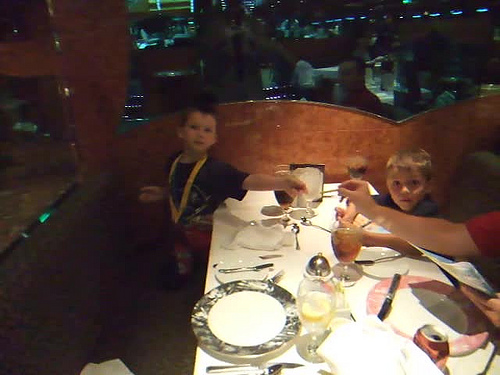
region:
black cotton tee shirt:
[164, 159, 246, 227]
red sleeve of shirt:
[467, 205, 499, 254]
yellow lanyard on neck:
[163, 154, 210, 226]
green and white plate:
[195, 280, 299, 357]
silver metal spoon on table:
[303, 219, 330, 238]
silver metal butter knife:
[379, 272, 400, 319]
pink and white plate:
[368, 275, 492, 355]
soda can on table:
[411, 324, 450, 371]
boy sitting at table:
[366, 149, 442, 220]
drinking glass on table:
[331, 222, 363, 285]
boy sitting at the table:
[157, 103, 255, 250]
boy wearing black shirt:
[144, 94, 255, 254]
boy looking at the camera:
[366, 134, 438, 241]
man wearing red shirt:
[322, 48, 392, 129]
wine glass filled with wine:
[290, 269, 340, 360]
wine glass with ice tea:
[330, 211, 375, 286]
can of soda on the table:
[409, 318, 453, 363]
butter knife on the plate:
[217, 256, 282, 280]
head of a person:
[174, 92, 228, 157]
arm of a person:
[132, 173, 172, 213]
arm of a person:
[220, 149, 284, 203]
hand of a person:
[280, 159, 315, 197]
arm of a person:
[374, 191, 468, 255]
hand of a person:
[324, 168, 379, 220]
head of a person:
[364, 129, 445, 214]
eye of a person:
[382, 166, 434, 191]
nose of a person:
[395, 182, 416, 202]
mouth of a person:
[392, 196, 416, 210]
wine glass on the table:
[327, 219, 366, 284]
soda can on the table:
[410, 321, 454, 373]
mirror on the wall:
[10, 66, 92, 221]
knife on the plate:
[219, 253, 276, 278]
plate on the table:
[185, 277, 304, 361]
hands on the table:
[328, 176, 374, 227]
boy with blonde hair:
[378, 144, 438, 215]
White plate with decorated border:
[188, 277, 295, 358]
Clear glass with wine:
[297, 277, 336, 366]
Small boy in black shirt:
[142, 109, 310, 276]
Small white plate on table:
[215, 250, 269, 283]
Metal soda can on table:
[419, 323, 452, 371]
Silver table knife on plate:
[378, 263, 404, 325]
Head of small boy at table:
[383, 146, 436, 212]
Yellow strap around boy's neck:
[163, 153, 206, 217]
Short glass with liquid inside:
[329, 220, 364, 283]